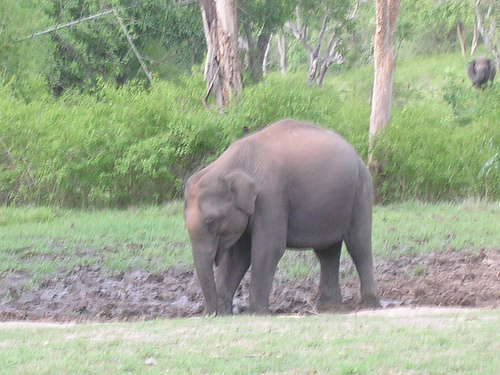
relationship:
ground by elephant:
[382, 220, 468, 257] [177, 90, 396, 246]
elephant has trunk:
[177, 90, 396, 246] [189, 245, 238, 310]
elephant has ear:
[177, 90, 396, 246] [234, 168, 269, 214]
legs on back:
[224, 238, 396, 322] [313, 187, 419, 309]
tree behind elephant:
[185, 34, 220, 99] [177, 90, 396, 246]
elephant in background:
[177, 90, 396, 246] [76, 18, 423, 152]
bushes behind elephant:
[37, 57, 159, 152] [177, 90, 396, 246]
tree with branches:
[185, 34, 220, 99] [248, 3, 362, 79]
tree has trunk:
[185, 34, 220, 99] [200, 0, 289, 115]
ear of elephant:
[234, 168, 269, 214] [177, 90, 396, 246]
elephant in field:
[177, 90, 396, 246] [15, 201, 402, 371]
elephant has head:
[177, 90, 396, 246] [172, 178, 243, 240]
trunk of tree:
[200, 65, 288, 115] [185, 34, 220, 99]